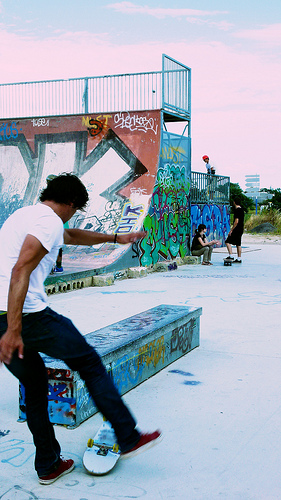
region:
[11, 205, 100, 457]
a man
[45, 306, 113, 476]
a man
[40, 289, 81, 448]
a man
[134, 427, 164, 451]
red and white sneakers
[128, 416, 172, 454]
red and white sneakers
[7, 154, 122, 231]
man with short dark hair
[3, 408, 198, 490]
man wearing pair or red tennis shoes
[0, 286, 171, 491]
man wearing pair of blue jeans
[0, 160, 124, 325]
man wearing white tee shirt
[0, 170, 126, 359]
man wearing short sleeve white shirt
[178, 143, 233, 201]
person wearing red safety helmet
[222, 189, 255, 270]
person wearing black short sleeve shirt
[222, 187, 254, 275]
man wearing pair of white socks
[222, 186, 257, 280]
man wearing black tennis shoes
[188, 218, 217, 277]
woman wearing pair of sandals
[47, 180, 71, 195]
Man has black hair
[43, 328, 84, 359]
Man wearing blue jeans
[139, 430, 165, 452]
Man wearing red sneakers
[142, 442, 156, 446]
White side of sneakers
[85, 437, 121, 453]
Yellow wheels on skateboard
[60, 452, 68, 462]
White shoe strings on sneakers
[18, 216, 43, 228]
Man wearing white shirt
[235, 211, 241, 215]
Man wearing black shirt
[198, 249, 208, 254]
Woman wearing olive green jeans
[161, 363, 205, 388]
Blue paint on ground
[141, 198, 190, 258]
graffiti art on wall